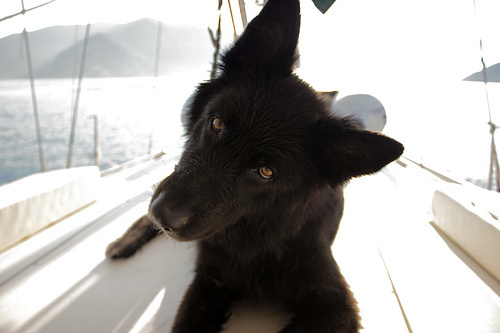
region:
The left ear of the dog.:
[233, 2, 300, 74]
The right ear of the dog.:
[316, 120, 398, 185]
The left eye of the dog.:
[207, 106, 234, 137]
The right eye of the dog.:
[251, 155, 276, 187]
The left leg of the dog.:
[173, 261, 215, 331]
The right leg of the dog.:
[275, 291, 350, 329]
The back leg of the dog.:
[96, 212, 168, 267]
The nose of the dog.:
[154, 192, 186, 229]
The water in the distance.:
[8, 70, 204, 163]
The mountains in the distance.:
[5, 20, 204, 77]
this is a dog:
[92, 0, 409, 331]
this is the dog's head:
[143, 0, 405, 240]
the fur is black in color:
[235, 80, 280, 130]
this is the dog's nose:
[146, 180, 196, 231]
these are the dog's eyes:
[206, 110, 283, 185]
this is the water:
[3, 95, 25, 164]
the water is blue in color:
[1, 138, 30, 171]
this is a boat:
[38, 177, 75, 312]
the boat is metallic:
[34, 174, 90, 314]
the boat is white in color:
[43, 267, 72, 289]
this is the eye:
[250, 160, 275, 180]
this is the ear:
[215, 5, 315, 82]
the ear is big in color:
[220, 1, 310, 78]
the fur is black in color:
[256, 104, 309, 132]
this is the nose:
[151, 190, 188, 222]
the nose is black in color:
[148, 197, 183, 224]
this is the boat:
[382, 227, 449, 289]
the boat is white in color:
[377, 222, 452, 292]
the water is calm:
[107, 98, 135, 148]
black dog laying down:
[110, 0, 362, 330]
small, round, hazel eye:
[258, 161, 276, 181]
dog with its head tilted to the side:
[120, 1, 401, 285]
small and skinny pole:
[86, 112, 103, 159]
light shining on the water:
[48, 78, 157, 141]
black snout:
[138, 135, 245, 255]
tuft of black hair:
[340, 112, 363, 129]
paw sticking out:
[86, 198, 157, 260]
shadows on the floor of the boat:
[32, 236, 204, 331]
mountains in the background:
[1, 13, 194, 86]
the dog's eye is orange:
[263, 166, 273, 183]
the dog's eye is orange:
[264, 168, 269, 173]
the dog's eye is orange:
[264, 168, 269, 179]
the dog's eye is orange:
[261, 165, 271, 195]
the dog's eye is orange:
[257, 161, 275, 198]